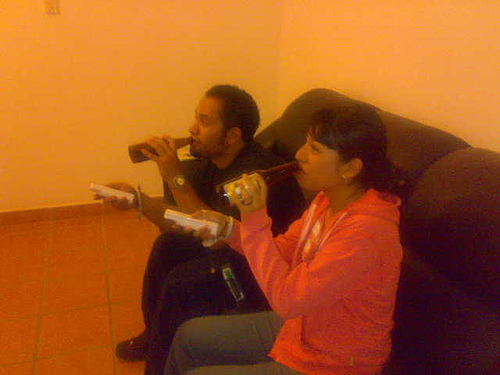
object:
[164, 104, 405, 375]
girl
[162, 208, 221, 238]
remote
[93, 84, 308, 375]
man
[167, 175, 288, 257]
left arm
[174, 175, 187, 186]
watch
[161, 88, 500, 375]
couch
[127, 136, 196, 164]
beer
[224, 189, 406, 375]
hoodie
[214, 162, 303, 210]
beer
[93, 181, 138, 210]
hand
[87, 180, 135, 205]
controller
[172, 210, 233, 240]
hand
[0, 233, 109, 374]
floor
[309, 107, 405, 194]
hair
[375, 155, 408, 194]
pony tail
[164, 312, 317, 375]
jeans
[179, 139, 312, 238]
shirt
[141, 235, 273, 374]
pants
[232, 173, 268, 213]
hand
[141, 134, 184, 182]
hand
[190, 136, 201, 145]
mouth